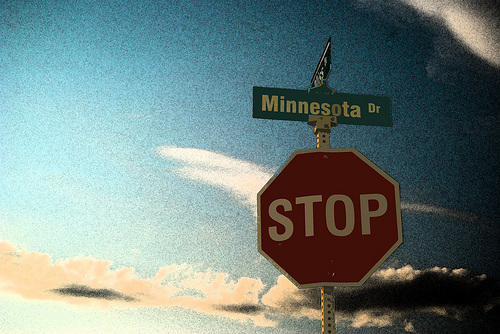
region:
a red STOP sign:
[229, 138, 406, 303]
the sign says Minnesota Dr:
[247, 85, 398, 132]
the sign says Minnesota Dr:
[230, 66, 414, 147]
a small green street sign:
[302, 44, 343, 81]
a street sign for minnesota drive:
[254, 75, 399, 137]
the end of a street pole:
[300, 107, 342, 137]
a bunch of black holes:
[316, 131, 331, 151]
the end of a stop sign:
[291, 144, 313, 157]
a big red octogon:
[221, 151, 421, 284]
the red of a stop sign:
[285, 159, 329, 189]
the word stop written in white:
[263, 194, 385, 249]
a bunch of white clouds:
[81, 232, 198, 312]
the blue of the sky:
[24, 105, 103, 173]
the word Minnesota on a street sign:
[258, 92, 362, 119]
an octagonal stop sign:
[254, 153, 405, 287]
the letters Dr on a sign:
[366, 101, 380, 113]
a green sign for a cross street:
[303, 40, 337, 87]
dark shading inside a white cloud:
[44, 281, 136, 302]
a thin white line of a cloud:
[398, 198, 465, 223]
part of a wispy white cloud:
[156, 142, 274, 210]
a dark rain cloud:
[306, 268, 498, 331]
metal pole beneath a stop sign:
[319, 285, 336, 331]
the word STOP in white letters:
[269, 194, 386, 241]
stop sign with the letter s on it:
[253, 137, 400, 310]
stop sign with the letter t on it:
[253, 139, 408, 306]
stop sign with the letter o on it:
[251, 144, 410, 320]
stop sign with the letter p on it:
[251, 143, 413, 305]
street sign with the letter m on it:
[223, 70, 414, 149]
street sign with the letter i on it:
[219, 77, 429, 165]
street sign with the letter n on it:
[212, 75, 425, 148]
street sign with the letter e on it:
[217, 67, 434, 161]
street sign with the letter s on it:
[236, 53, 442, 168]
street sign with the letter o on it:
[215, 72, 426, 160]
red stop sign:
[250, 144, 409, 296]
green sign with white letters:
[249, 77, 396, 127]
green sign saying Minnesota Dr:
[249, 76, 397, 128]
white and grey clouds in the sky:
[0, 237, 264, 331]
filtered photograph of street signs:
[7, 5, 497, 330]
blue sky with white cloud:
[27, 121, 255, 213]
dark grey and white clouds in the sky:
[339, 268, 495, 330]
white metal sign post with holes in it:
[300, 284, 355, 332]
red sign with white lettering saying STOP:
[256, 148, 408, 292]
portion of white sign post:
[306, 112, 341, 149]